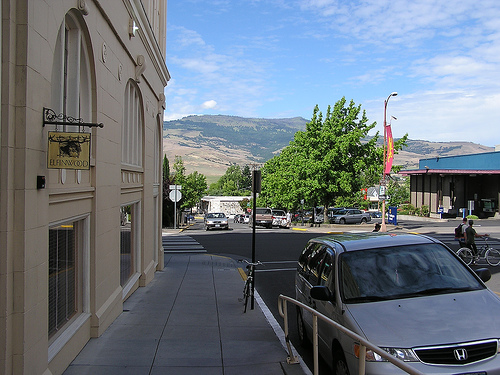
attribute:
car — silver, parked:
[295, 231, 499, 369]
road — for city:
[163, 233, 499, 369]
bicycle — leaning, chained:
[240, 259, 261, 309]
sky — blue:
[164, 1, 498, 149]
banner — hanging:
[384, 124, 393, 174]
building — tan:
[1, 4, 170, 374]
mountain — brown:
[164, 116, 498, 185]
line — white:
[164, 250, 207, 253]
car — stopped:
[206, 210, 230, 228]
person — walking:
[466, 221, 481, 257]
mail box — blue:
[388, 205, 396, 224]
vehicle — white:
[272, 208, 287, 226]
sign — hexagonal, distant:
[169, 189, 183, 203]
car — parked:
[333, 208, 374, 222]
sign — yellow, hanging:
[47, 132, 91, 172]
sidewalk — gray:
[63, 252, 309, 373]